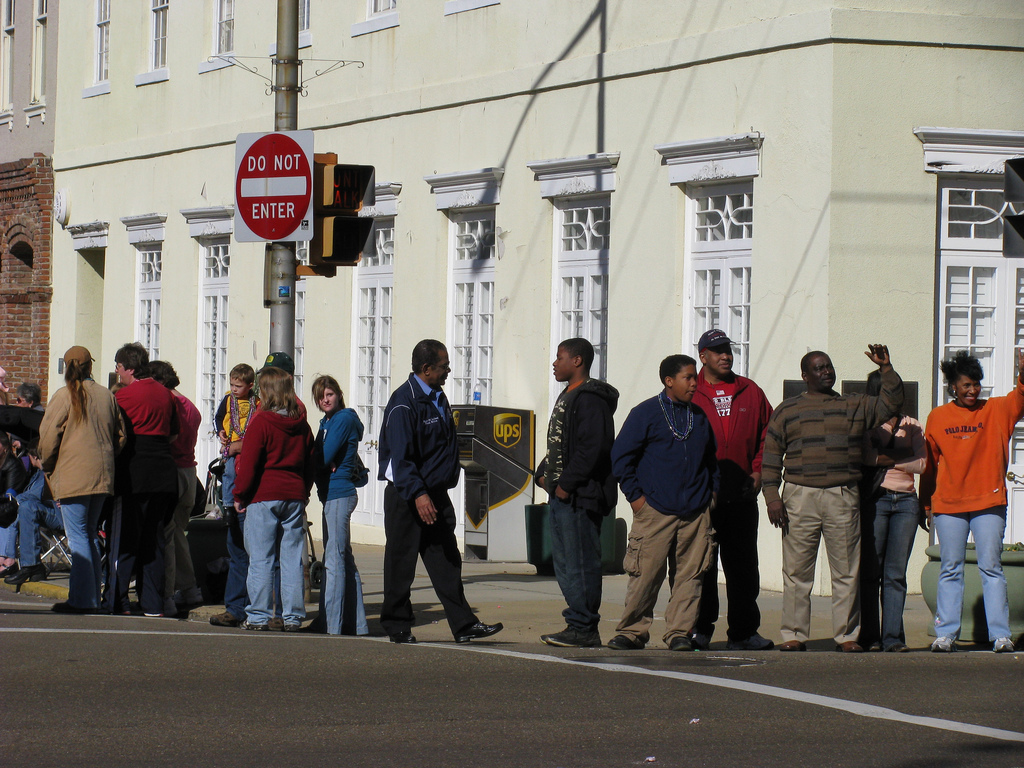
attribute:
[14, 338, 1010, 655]
people — waiting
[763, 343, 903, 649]
man — waving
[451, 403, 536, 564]
box — brown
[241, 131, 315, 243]
sign — red, white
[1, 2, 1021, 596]
wall — white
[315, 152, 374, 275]
light — electronic, yellow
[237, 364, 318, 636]
woman — smiling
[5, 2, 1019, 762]
weather — nice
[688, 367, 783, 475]
jacket — red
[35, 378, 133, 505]
jacket — brown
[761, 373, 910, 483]
sweather — brown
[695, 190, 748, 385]
windows — white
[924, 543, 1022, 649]
pot — green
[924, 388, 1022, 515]
sweater — orange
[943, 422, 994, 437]
letters — blue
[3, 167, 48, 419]
building — brick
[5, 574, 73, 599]
paint — yellow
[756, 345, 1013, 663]
people — waving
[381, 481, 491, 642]
pants — black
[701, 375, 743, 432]
shirt — red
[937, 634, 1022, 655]
shoes — white